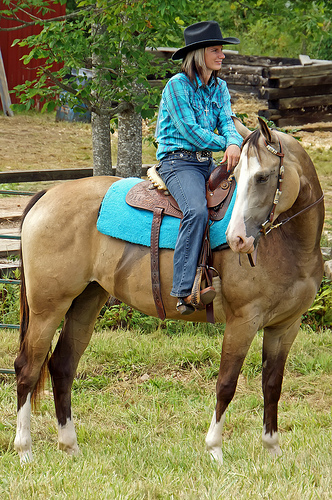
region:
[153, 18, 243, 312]
Young woman on beige horse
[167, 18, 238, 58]
Black hat on horsewoman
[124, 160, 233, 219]
Brown saddle on beige horse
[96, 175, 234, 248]
Blue blanket under brown saddle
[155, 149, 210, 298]
Blue jeans on horsewoman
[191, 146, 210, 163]
Silver buckle on horsewoman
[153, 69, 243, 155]
Blue shirt on a horsewoman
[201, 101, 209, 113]
Cross necklace on horsewoman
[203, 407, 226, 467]
White stocking on beige horse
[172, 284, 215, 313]
Brown boot worn by a horsewoman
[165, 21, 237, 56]
the hat is black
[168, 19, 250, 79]
the hat is black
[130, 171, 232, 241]
the saddle is brown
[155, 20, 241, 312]
a woman in a blue plaid cowboy shirt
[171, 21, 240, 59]
a black felt cowboy hat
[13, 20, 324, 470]
a woman riding a tan horse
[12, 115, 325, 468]
a tan horse with white and black markings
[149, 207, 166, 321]
a brown leather saddle strap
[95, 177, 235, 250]
a blue saddle blanket under saddle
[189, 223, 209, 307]
a brown leather strap to stirrup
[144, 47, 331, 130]
a grey wooden split rail fence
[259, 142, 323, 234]
a brown leather halter and bridle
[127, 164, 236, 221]
a brown leather horse saddle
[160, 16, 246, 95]
a woman wearing a black hat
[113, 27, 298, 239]
a woman sitting on a horse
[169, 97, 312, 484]
a horse with his head turned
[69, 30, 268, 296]
a horse wearing a saddle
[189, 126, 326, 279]
a horse wearing a bridle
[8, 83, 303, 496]
a brown horse with white feet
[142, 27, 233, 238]
a woman wearing blue jeans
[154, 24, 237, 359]
a woman with her foot in a stirrup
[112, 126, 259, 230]
a leather saddle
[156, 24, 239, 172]
a woman wearing a blue shirt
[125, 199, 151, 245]
aqua blanket under saddle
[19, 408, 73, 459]
bottom part of horse's legs are white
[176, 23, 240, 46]
woman is wearing a cowboy hat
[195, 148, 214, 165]
woman is wearing a big belt buckle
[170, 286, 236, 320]
boot in the stirup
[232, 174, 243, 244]
horse has white on his nose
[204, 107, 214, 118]
woman has a cross on her necklace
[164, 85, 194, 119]
shirt is plaid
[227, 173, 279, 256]
horse turned it's head to the right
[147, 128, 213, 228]
woman sitting on the horse